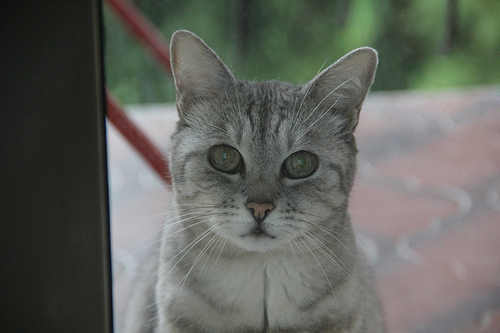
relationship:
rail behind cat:
[98, 1, 163, 73] [115, 26, 389, 332]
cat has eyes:
[115, 26, 389, 332] [280, 149, 320, 180]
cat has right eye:
[115, 26, 389, 332] [207, 141, 242, 176]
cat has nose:
[115, 26, 389, 332] [248, 198, 272, 221]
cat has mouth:
[115, 26, 389, 332] [235, 224, 276, 240]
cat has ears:
[115, 26, 389, 332] [167, 28, 244, 100]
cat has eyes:
[115, 26, 389, 332] [204, 142, 320, 179]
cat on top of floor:
[115, 26, 389, 332] [108, 84, 499, 332]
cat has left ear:
[115, 26, 389, 332] [302, 40, 378, 128]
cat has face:
[115, 26, 389, 332] [197, 124, 325, 249]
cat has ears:
[115, 26, 389, 332] [167, 28, 379, 115]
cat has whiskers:
[115, 26, 389, 332] [280, 209, 372, 305]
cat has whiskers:
[115, 26, 389, 332] [122, 201, 234, 322]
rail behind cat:
[103, 93, 172, 186] [115, 26, 389, 332]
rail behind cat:
[110, 1, 170, 73] [115, 26, 389, 332]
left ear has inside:
[302, 40, 378, 128] [315, 51, 372, 108]